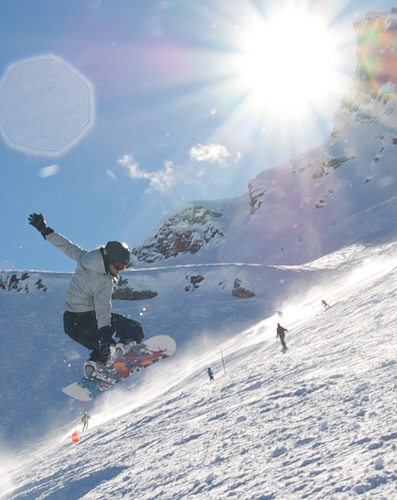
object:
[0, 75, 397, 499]
snow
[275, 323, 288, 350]
people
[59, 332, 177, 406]
board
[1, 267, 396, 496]
snowy hill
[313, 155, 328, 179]
rock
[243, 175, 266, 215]
rock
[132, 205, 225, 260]
rock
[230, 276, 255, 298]
rock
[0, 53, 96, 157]
lens flare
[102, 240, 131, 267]
helmet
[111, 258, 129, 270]
goggles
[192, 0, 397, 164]
glares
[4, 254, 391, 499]
snow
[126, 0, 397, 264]
hill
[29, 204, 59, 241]
gloves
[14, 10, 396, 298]
sky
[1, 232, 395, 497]
slope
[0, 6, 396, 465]
mountain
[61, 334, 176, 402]
snowboard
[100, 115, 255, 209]
clouds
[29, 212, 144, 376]
person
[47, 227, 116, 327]
coat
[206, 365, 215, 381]
skier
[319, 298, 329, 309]
skier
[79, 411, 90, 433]
skier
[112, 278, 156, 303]
rock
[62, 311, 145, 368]
pants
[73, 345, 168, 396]
designs